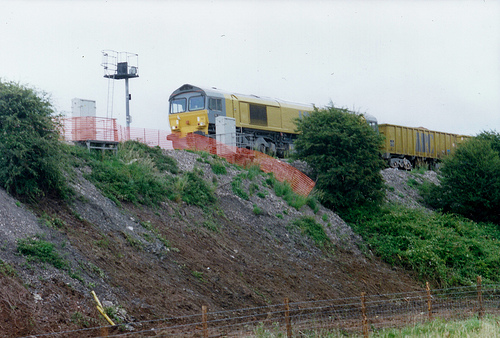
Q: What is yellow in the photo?
A: A train.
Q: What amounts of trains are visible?
A: One.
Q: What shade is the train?
A: Yellow.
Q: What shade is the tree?
A: Green.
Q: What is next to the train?
A: A bush.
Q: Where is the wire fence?
A: Bottom of the hill.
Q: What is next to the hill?
A: Dirt.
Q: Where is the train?
A: On the tracks.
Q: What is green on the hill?
A: Grass.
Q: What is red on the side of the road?
A: A fence.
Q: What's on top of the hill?
A: Train.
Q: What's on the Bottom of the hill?
A: Fence.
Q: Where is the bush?
A: Hill.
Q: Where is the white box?
A: Top of the hill.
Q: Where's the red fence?
A: Front of the train.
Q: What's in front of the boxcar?
A: Tree.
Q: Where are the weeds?
A: Hill.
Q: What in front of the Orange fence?
A: Weeds.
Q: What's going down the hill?
A: Orange fence.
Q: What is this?
A: A train.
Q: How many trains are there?
A: One.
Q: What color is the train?
A: Blue and orange.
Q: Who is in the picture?
A: No one.